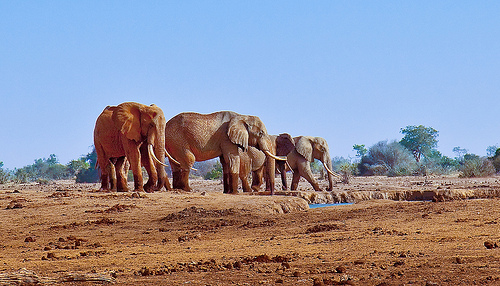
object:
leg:
[125, 148, 146, 192]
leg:
[140, 151, 157, 193]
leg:
[97, 158, 109, 193]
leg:
[114, 160, 129, 192]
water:
[309, 203, 353, 208]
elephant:
[93, 102, 197, 193]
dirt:
[95, 199, 135, 215]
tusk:
[145, 142, 199, 171]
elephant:
[165, 111, 287, 196]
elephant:
[237, 134, 294, 192]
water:
[394, 199, 432, 201]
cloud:
[271, 73, 319, 114]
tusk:
[286, 161, 295, 173]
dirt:
[482, 238, 500, 248]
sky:
[0, 0, 500, 171]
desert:
[0, 171, 500, 286]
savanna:
[0, 125, 500, 286]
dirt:
[139, 252, 289, 271]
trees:
[351, 125, 499, 176]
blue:
[0, 0, 500, 171]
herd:
[93, 101, 339, 195]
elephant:
[278, 136, 341, 192]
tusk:
[265, 150, 288, 160]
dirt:
[162, 200, 238, 226]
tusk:
[323, 163, 341, 179]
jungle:
[0, 125, 500, 183]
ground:
[2, 172, 499, 286]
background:
[0, 0, 500, 286]